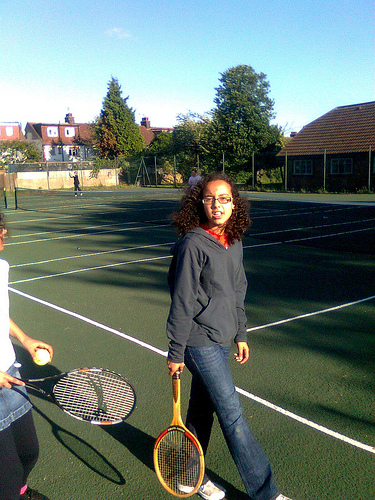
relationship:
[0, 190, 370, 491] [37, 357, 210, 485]
two people carrying rackets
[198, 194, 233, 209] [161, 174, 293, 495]
glasses on young lady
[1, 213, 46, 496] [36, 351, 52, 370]
person holding tennis ball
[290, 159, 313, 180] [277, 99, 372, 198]
window on building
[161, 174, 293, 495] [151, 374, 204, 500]
young lady holding tennis racket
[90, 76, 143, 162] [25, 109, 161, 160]
tree near another building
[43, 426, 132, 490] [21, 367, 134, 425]
shadow of tennis racket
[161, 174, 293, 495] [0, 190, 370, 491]
young lady on court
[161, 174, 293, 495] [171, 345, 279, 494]
young lady wearing jeans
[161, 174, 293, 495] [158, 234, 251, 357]
young lady wearing sweatshirt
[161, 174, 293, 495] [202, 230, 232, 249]
young lady wearing undershirt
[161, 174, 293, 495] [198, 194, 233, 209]
young lady wearing glasses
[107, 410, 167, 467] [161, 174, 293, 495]
shadow of young lady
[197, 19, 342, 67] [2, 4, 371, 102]
part of sky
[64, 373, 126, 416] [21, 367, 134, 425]
part of tennis racket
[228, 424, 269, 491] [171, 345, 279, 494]
part of jeans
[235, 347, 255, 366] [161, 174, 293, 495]
left hand on young lady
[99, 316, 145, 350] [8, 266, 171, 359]
part of white line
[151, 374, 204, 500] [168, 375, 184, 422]
tennis racket has handle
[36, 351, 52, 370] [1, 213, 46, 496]
tennis ball with person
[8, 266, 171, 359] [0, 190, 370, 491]
white line on court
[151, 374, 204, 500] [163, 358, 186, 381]
tennis racket in right hand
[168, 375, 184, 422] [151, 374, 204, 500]
handle of tennis racket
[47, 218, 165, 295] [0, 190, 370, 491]
patch of court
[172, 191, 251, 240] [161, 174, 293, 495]
hair on young lady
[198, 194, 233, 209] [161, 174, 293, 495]
glasses on person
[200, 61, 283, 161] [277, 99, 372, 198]
large tree near building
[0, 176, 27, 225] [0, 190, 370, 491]
net on court